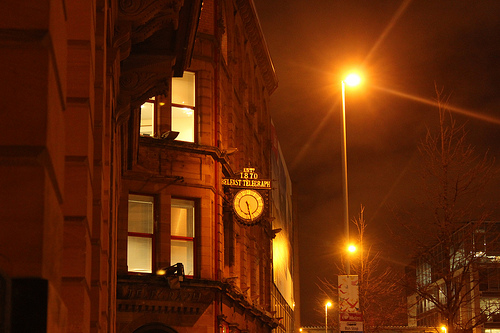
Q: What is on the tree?
A: Branches only.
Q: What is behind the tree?
A: A building.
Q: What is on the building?
A: Bricks.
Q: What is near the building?
A: Street lights.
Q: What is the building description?
A: Multi story.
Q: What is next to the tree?
A: Light post.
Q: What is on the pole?
A: Street lights.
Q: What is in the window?
A: Lights.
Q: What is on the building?
A: Clock.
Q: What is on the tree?
A: Branches only.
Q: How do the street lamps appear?
A: Orange and with distorted auras.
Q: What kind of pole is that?
A: A lamp post.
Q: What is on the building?
A: A metal clock.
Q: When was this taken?
A: During a cloudy night.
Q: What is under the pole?
A: A red and white sign.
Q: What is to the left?
A: A building with lights on.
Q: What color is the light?
A: Orange.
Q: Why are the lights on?
A: It is dark outside.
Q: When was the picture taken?
A: At night.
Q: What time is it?
A: 5:27.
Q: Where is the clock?
A: Hanging on the building.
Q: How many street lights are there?
A: 3.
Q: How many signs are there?
A: 1.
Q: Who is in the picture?
A: No one.